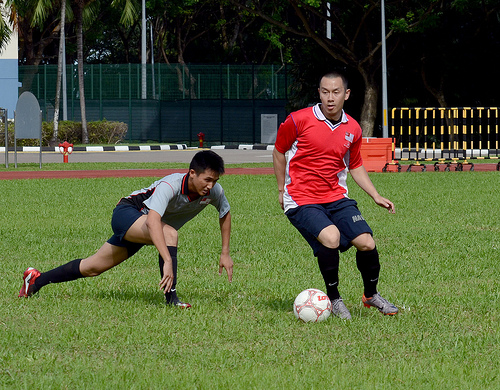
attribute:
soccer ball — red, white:
[288, 282, 335, 329]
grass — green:
[417, 200, 473, 270]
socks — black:
[354, 250, 380, 302]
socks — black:
[317, 246, 339, 296]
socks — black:
[158, 243, 175, 300]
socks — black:
[33, 257, 82, 285]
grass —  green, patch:
[1, 160, 274, 173]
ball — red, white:
[291, 283, 333, 322]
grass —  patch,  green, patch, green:
[1, 172, 498, 389]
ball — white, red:
[289, 280, 330, 324]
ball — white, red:
[270, 277, 343, 331]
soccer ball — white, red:
[292, 282, 332, 324]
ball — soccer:
[268, 271, 361, 332]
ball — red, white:
[291, 287, 333, 323]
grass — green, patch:
[117, 296, 293, 389]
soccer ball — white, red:
[292, 288, 334, 325]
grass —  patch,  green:
[434, 203, 478, 288]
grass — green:
[207, 315, 227, 335]